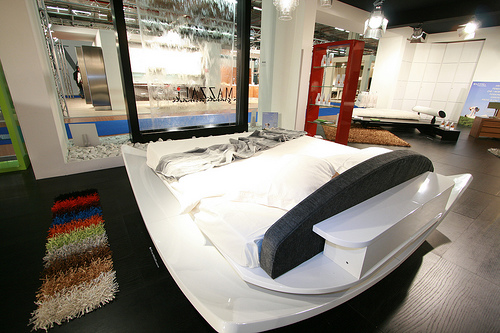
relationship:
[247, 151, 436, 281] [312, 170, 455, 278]
headboard leaning on shelf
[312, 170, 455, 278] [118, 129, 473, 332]
shelf attached to bed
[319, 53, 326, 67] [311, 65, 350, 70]
bottle on shelf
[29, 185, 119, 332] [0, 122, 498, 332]
carpet on ground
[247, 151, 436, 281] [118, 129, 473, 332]
headboard for bed